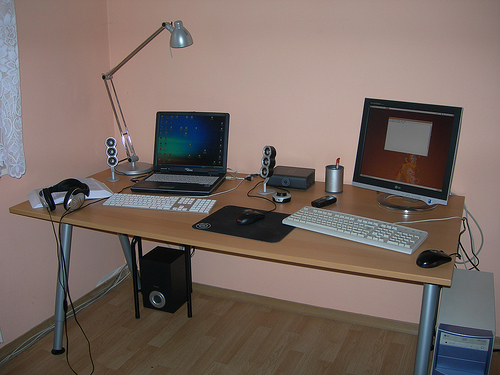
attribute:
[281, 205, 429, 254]
keyboard — white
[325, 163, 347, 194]
can — pencil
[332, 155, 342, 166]
pen — single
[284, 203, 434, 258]
laptop — white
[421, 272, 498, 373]
computer — tower 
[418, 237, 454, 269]
mouse — right side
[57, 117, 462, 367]
table — right side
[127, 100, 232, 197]
computer — black laptop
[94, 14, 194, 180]
lamp — tall silver desk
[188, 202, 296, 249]
pad — large mouse 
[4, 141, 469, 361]
desk — tan 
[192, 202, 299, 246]
mouse pad — black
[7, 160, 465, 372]
desk — tan, set up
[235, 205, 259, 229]
mouse — black 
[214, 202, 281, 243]
pad — black mouse 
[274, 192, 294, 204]
mouse — black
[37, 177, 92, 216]
headphones — large black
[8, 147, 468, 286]
desk — tan 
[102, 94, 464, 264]
computers —  two 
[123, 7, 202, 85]
lamp — hinged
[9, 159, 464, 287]
desk — wooden 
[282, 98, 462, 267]
computer — desktop 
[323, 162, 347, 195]
pencil holder — pencil 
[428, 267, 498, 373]
cpu computer — tan, blue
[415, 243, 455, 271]
computer mouse — black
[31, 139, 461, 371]
table — middle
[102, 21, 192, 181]
lamp — Silver